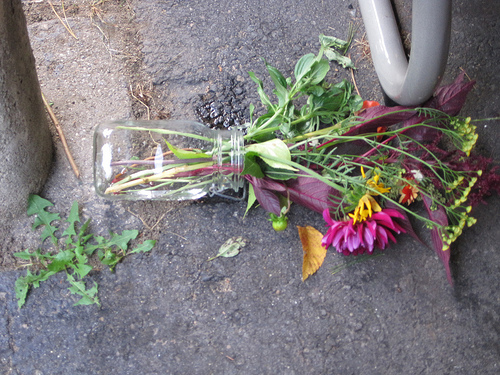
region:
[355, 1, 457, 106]
White metal support leg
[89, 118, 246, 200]
Glass jar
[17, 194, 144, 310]
Dandelion growing in a crack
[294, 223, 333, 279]
Yellow leaf on the concrete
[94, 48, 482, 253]
Glass jar with flowers lying on it's side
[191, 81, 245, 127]
Spilled water on the ground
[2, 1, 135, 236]
Concrete post and base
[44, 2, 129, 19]
Dead grass on the ground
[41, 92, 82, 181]
Brown twig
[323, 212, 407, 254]
A purple flower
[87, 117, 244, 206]
clear glass jar with flowers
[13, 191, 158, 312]
a dandelion grows through the pavement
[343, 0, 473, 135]
bent leg of a lawn chair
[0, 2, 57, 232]
portion of a concree post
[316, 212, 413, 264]
pink flower resembles a dahlia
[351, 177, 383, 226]
a young black eyed susan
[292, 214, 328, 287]
a dried yellowed leaf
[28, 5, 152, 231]
foundation of concrete post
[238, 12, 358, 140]
mixed green leaves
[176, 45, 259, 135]
a spot shows where water spilled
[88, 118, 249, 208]
a glass mason jar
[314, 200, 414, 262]
a pink flower on the ground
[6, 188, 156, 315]
a green plant on the ground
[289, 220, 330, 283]
a yellow leaf on the ground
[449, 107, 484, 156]
yellow flowers on the ground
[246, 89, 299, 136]
the stem of a plant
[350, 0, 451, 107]
a white metal bar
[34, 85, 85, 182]
a brown stick on the ground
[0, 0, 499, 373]
a gray paved ground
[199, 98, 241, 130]
water on the pavement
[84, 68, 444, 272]
the vase on the gournd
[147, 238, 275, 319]
the small leaf by itself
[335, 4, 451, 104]
some sort of handle bar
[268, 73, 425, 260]
a bunch of flowers on the ground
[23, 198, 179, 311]
the leaf on the side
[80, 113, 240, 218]
the vase that looks like a jar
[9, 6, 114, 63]
some leafy stuff on the side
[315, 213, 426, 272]
the purple flower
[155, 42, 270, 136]
the weird crack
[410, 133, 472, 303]
cool stuff on the side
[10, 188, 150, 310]
weed growing out of the ground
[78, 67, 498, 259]
spilled glass of flowers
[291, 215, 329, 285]
dried yellow flower on ground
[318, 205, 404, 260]
pink petals on the ground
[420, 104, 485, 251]
tiny yellow flowers in a bouquet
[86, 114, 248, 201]
glass jar being used as a vase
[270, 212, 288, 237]
small green berry on a stem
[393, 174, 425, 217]
orange flower dying on the ground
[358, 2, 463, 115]
curved metal piece of bike rack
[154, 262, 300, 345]
pitted surface of asphalt